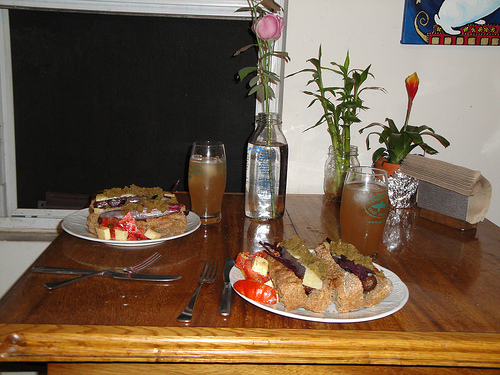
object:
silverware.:
[23, 250, 233, 325]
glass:
[339, 165, 390, 263]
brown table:
[0, 192, 499, 375]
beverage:
[338, 166, 389, 264]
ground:
[0, 239, 22, 275]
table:
[0, 192, 500, 372]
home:
[1, 0, 500, 373]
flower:
[251, 14, 284, 40]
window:
[7, 4, 257, 219]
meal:
[233, 236, 393, 313]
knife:
[219, 254, 235, 317]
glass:
[244, 112, 290, 221]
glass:
[188, 140, 227, 225]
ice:
[193, 155, 220, 170]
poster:
[395, 1, 499, 49]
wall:
[284, 3, 494, 150]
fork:
[176, 260, 220, 322]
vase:
[243, 111, 289, 220]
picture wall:
[394, 0, 500, 54]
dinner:
[234, 237, 393, 314]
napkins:
[395, 154, 492, 229]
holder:
[398, 151, 493, 231]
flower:
[308, 52, 371, 141]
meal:
[88, 183, 189, 240]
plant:
[359, 72, 451, 170]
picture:
[399, 0, 497, 48]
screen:
[13, 6, 262, 218]